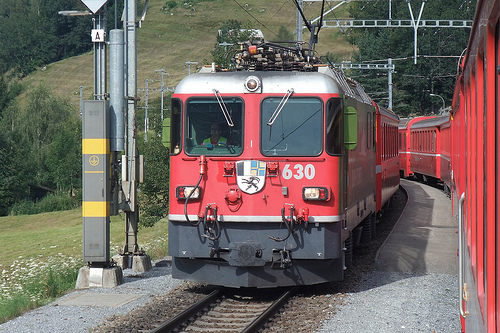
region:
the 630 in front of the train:
[282, 164, 314, 179]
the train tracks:
[145, 287, 282, 332]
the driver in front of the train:
[200, 123, 229, 145]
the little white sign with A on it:
[91, 30, 102, 41]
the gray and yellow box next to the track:
[81, 100, 109, 262]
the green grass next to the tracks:
[12, 218, 66, 245]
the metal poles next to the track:
[107, 5, 149, 274]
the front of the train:
[171, 74, 338, 284]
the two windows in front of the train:
[182, 95, 320, 161]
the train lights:
[175, 183, 329, 202]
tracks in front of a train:
[147, 278, 302, 326]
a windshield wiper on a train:
[265, 85, 290, 132]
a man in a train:
[191, 116, 231, 148]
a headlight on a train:
[300, 180, 340, 201]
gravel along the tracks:
[287, 286, 462, 326]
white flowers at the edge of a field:
[0, 235, 77, 301]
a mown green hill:
[11, 0, 356, 142]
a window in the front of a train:
[258, 92, 330, 167]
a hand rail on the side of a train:
[443, 182, 480, 331]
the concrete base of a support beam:
[66, 259, 134, 289]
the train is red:
[117, 20, 428, 296]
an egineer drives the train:
[139, 36, 254, 165]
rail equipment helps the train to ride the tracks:
[48, 5, 163, 296]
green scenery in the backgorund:
[14, 7, 173, 209]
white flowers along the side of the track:
[7, 249, 140, 311]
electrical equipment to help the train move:
[288, 2, 470, 114]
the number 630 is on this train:
[238, 151, 346, 207]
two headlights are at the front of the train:
[166, 157, 348, 238]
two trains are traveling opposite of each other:
[160, 26, 496, 316]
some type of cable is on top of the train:
[168, 20, 432, 162]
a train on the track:
[166, 67, 347, 286]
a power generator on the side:
[58, 37, 140, 281]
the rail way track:
[186, 292, 283, 332]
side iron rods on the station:
[416, 86, 495, 306]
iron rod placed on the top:
[291, 7, 469, 44]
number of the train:
[266, 160, 321, 183]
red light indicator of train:
[243, 67, 268, 92]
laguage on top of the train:
[196, 22, 319, 77]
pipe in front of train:
[188, 173, 219, 253]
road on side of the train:
[401, 181, 455, 331]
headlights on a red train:
[165, 178, 347, 220]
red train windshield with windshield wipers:
[160, 73, 360, 165]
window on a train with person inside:
[173, 88, 253, 166]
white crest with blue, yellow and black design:
[232, 157, 269, 200]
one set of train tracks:
[128, 273, 308, 332]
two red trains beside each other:
[310, 30, 492, 327]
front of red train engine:
[167, 57, 351, 304]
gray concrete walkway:
[371, 188, 462, 283]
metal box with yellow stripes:
[70, 93, 115, 265]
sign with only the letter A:
[85, 26, 110, 48]